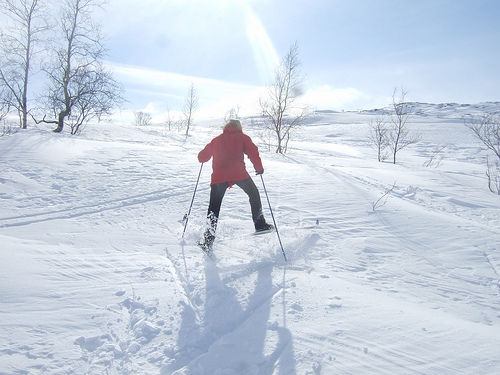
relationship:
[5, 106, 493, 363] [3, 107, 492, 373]
snow on ground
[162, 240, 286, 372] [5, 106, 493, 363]
tracks in snow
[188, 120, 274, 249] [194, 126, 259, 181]
person wearing jacket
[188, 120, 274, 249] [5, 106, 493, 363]
person in snow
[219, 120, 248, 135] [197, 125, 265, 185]
hood on jacket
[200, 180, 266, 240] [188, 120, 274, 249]
pants on person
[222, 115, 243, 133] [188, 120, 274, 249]
head on person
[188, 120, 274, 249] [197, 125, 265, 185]
person wearing jacket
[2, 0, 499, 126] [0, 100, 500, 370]
clouds in sky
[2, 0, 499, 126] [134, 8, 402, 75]
clouds in sky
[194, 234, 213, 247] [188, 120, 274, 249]
foot on person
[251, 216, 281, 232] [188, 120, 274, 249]
foot on person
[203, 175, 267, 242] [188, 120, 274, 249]
pants on person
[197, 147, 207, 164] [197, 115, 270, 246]
elbow on man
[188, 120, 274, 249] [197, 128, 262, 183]
person wears coat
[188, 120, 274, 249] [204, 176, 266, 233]
person wears pants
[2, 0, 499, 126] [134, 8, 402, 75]
clouds are in sky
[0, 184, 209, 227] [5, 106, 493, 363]
track left in snow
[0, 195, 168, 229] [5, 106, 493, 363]
track left in snow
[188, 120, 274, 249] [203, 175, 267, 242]
person wearing pants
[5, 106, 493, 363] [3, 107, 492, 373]
snow covering ground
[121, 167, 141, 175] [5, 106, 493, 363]
footprint left in snow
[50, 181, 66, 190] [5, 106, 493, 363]
footprint left in snow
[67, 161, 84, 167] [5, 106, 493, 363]
footprint left in snow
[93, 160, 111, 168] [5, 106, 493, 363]
footprint left in snow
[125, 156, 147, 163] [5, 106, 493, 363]
footprint left in snow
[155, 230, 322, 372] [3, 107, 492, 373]
shadow casted on ground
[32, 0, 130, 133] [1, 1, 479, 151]
tree standing in background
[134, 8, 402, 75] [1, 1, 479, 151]
sky seen in background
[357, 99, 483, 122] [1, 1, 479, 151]
mountain seen in background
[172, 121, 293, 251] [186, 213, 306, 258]
person wearing skis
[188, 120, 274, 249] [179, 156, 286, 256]
person holding pole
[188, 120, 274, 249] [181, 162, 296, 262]
person holding pole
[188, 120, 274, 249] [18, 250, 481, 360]
person skiing snow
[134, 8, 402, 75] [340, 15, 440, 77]
sky with clouds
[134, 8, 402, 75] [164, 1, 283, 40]
sky with clouds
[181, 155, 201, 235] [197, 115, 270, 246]
pole for man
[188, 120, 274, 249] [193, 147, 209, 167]
person has hand